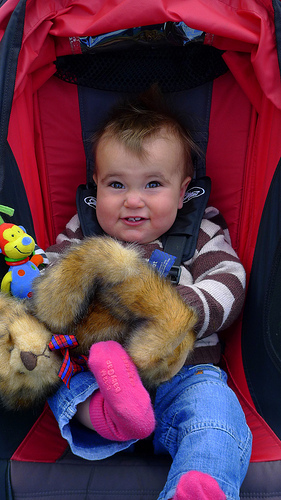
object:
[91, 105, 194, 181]
hair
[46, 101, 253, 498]
baby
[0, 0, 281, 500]
stroller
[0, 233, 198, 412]
bear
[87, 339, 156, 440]
sock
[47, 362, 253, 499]
jeans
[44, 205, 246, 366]
shirt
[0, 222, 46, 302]
bug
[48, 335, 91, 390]
ribbon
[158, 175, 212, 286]
strap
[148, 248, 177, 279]
tag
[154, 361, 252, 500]
leg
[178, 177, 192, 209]
ear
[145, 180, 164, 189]
eye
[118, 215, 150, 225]
mouth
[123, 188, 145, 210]
nose